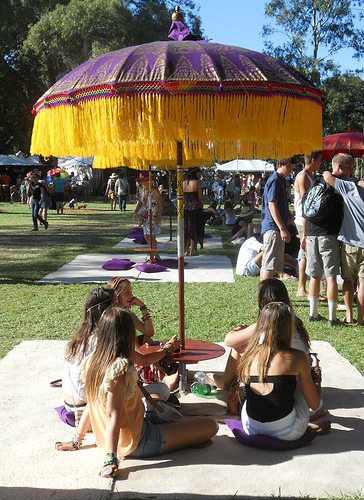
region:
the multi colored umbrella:
[30, 4, 324, 160]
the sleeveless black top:
[241, 373, 297, 421]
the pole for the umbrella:
[28, 5, 323, 348]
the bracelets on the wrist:
[71, 430, 85, 449]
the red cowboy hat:
[135, 171, 155, 182]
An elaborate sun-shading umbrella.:
[26, 3, 326, 397]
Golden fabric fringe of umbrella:
[26, 90, 326, 171]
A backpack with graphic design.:
[298, 175, 337, 226]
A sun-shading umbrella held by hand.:
[40, 164, 69, 183]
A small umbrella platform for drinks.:
[137, 335, 225, 366]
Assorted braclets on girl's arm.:
[138, 304, 153, 323]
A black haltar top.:
[241, 368, 299, 425]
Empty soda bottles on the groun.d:
[188, 367, 219, 398]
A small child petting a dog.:
[66, 194, 88, 211]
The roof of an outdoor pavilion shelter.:
[214, 156, 277, 174]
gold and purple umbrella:
[25, 41, 325, 155]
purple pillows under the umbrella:
[102, 251, 186, 273]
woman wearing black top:
[231, 306, 330, 442]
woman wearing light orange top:
[59, 314, 212, 475]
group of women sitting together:
[57, 273, 335, 476]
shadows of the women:
[85, 353, 362, 477]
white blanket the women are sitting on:
[2, 336, 362, 495]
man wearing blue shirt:
[259, 155, 290, 290]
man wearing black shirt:
[297, 156, 359, 318]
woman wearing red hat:
[134, 167, 170, 258]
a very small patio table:
[139, 337, 223, 361]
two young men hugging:
[303, 152, 362, 326]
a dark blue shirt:
[263, 171, 288, 230]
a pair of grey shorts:
[257, 228, 283, 272]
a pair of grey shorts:
[303, 234, 337, 276]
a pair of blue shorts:
[245, 259, 258, 276]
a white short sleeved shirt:
[235, 237, 261, 274]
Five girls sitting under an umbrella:
[22, 2, 331, 483]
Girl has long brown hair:
[234, 294, 299, 386]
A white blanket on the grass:
[26, 242, 234, 286]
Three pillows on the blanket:
[96, 247, 188, 276]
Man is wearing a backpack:
[296, 144, 354, 237]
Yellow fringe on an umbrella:
[22, 88, 323, 173]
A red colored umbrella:
[312, 123, 361, 164]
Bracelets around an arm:
[94, 445, 122, 471]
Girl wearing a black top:
[232, 297, 323, 427]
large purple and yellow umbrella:
[24, 10, 316, 189]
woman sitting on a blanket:
[75, 308, 198, 467]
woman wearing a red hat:
[127, 163, 168, 265]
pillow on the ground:
[141, 262, 162, 276]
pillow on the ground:
[52, 399, 85, 430]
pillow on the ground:
[162, 253, 187, 276]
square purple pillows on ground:
[103, 252, 169, 278]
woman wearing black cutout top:
[237, 300, 323, 441]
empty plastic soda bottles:
[187, 365, 221, 397]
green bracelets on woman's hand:
[97, 447, 119, 479]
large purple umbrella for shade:
[28, 3, 323, 387]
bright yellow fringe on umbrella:
[30, 91, 332, 167]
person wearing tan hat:
[103, 169, 118, 209]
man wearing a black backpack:
[303, 172, 344, 228]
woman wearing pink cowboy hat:
[131, 168, 168, 264]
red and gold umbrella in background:
[323, 121, 362, 161]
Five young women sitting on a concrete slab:
[0, 274, 363, 497]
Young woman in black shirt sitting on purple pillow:
[221, 299, 330, 447]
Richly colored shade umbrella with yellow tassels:
[27, 1, 323, 157]